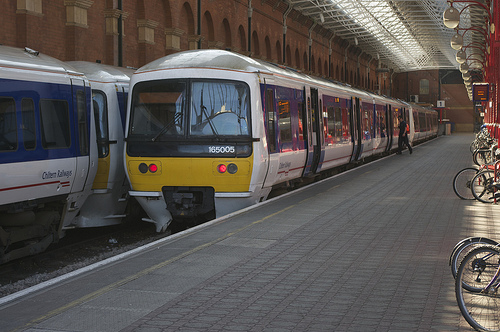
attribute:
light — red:
[214, 158, 234, 179]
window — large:
[125, 83, 177, 139]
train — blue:
[10, 55, 123, 237]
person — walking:
[393, 109, 421, 163]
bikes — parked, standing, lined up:
[465, 127, 499, 221]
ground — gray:
[156, 189, 469, 321]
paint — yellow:
[69, 282, 144, 298]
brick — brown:
[46, 7, 74, 58]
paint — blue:
[31, 85, 76, 102]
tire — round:
[450, 165, 484, 206]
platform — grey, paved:
[360, 125, 500, 312]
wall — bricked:
[17, 4, 415, 84]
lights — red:
[141, 160, 231, 180]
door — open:
[301, 87, 326, 175]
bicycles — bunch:
[454, 121, 499, 282]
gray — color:
[225, 246, 404, 329]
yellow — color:
[159, 159, 223, 187]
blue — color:
[18, 84, 90, 107]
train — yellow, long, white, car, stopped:
[123, 52, 439, 197]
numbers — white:
[209, 144, 237, 153]